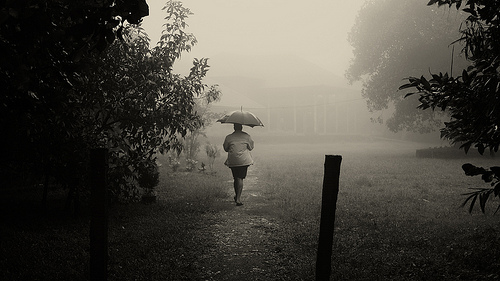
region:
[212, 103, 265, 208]
a woman with an umbrella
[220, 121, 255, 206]
the woman is wearing a skirt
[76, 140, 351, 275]
two wooden posts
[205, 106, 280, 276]
the woman is walking on a path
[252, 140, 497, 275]
grass is beside the path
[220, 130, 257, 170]
the woman is wearing a coat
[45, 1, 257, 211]
the woman is walking beside a tree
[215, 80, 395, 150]
a building in front of the woman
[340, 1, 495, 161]
a large tree on the right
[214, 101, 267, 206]
the woman is walking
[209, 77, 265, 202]
Woman is walking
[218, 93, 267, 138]
Woman is holding an umbrella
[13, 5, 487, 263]
Picture is in black and white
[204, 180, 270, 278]
Woman is walking along a path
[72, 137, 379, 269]
Two wooden posts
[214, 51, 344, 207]
The woman is walking toward a building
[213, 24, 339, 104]
Weather is very foggy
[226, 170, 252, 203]
Woman's legs are bare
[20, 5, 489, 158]
Trees on both the left and right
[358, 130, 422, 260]
Ground covered mostly in grass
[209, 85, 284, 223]
A woman walking in the rain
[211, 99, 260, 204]
A woman walking in the rain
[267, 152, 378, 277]
This is a picture of a pole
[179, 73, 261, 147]
this is a picture of an umbrella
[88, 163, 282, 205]
These are navy shorts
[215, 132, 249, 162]
This is a light jacket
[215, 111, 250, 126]
The umbrella is white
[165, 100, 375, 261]
The photo is black and white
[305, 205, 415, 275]
It is raining lightly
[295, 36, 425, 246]
The area is foggy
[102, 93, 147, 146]
This is an old tree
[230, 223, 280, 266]
This is a cobble path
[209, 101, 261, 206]
person walking down path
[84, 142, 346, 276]
posts on either side of path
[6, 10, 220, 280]
trees on left side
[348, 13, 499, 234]
trees on right side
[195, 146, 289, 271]
path person is walking down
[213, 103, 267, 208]
person walking and holding umbrella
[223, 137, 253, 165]
jacket of person walking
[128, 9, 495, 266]
rainy weather person is walking through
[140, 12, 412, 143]
misty air in the background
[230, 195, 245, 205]
shoes of person walking